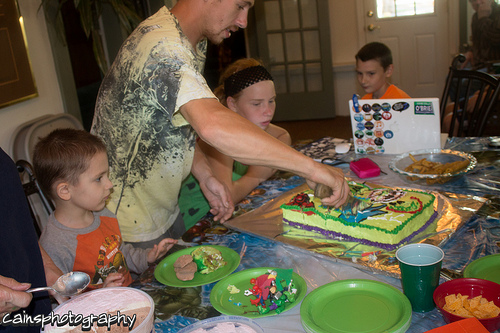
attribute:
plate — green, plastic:
[153, 242, 240, 284]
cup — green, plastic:
[392, 244, 446, 316]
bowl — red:
[434, 277, 499, 328]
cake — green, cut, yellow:
[283, 179, 439, 248]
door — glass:
[254, 1, 339, 124]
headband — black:
[223, 63, 280, 95]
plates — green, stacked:
[300, 276, 414, 331]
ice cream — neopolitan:
[86, 294, 131, 309]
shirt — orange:
[352, 87, 417, 151]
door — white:
[355, 1, 461, 115]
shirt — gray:
[40, 206, 141, 289]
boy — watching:
[349, 41, 414, 147]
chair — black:
[437, 54, 499, 135]